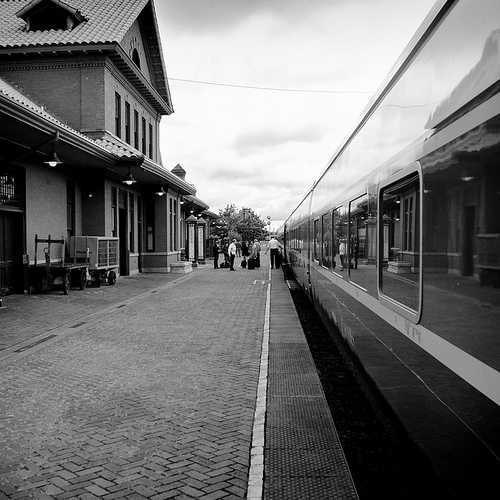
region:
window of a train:
[376, 183, 418, 263]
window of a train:
[352, 195, 373, 253]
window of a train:
[337, 210, 356, 267]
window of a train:
[311, 219, 333, 263]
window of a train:
[290, 230, 319, 259]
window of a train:
[282, 232, 294, 254]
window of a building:
[106, 90, 130, 135]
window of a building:
[122, 101, 139, 152]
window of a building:
[128, 103, 146, 155]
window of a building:
[127, 43, 150, 62]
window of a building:
[29, 11, 63, 28]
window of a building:
[132, 118, 153, 159]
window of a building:
[146, 202, 159, 246]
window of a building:
[132, 200, 142, 243]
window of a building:
[164, 201, 182, 252]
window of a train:
[295, 208, 345, 258]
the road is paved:
[135, 405, 180, 438]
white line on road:
[264, 284, 283, 494]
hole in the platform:
[328, 301, 381, 422]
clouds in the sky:
[212, 100, 276, 135]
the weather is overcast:
[272, 30, 359, 76]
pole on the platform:
[340, 175, 440, 310]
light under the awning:
[115, 164, 142, 194]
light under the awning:
[40, 143, 62, 180]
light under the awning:
[168, 193, 204, 210]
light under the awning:
[144, 183, 174, 205]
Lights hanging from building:
[28, 130, 208, 220]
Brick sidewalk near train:
[88, 340, 203, 499]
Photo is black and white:
[6, 58, 494, 492]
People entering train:
[208, 233, 293, 271]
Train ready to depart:
[273, 58, 498, 481]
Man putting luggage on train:
[263, 233, 283, 267]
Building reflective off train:
[292, 128, 499, 355]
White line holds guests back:
[252, 250, 276, 495]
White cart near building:
[71, 232, 123, 285]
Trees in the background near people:
[208, 198, 275, 260]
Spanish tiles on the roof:
[1, 1, 151, 162]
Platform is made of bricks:
[2, 247, 272, 499]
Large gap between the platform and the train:
[277, 251, 462, 499]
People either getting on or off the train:
[211, 232, 287, 273]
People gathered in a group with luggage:
[211, 234, 288, 271]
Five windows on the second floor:
[113, 94, 157, 162]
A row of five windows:
[111, 94, 156, 163]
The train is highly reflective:
[271, 93, 497, 499]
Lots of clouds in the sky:
[156, 94, 375, 234]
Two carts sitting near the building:
[25, 233, 120, 297]